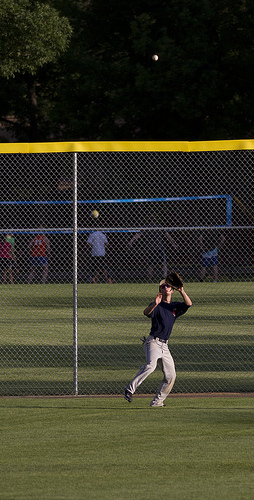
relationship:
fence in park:
[39, 180, 195, 353] [21, 53, 252, 405]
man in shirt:
[91, 227, 170, 396] [23, 235, 46, 278]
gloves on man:
[146, 274, 182, 303] [123, 267, 192, 407]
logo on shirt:
[167, 304, 182, 321] [23, 235, 46, 278]